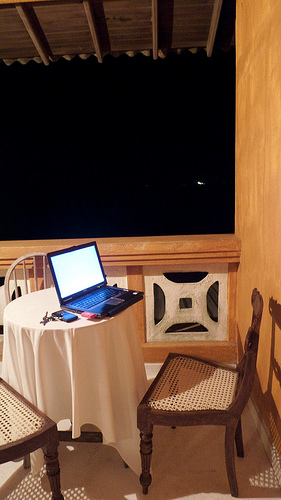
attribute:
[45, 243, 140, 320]
laptop — on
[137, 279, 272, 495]
chair — wooden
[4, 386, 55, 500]
chair — wooden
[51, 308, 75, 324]
cell phone — black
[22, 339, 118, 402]
cloth — white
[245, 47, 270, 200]
balcony — wood